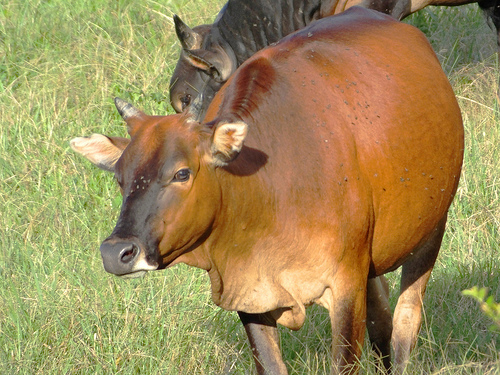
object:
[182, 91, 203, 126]
horn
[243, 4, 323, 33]
skin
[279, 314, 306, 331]
tip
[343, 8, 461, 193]
skin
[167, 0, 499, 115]
animal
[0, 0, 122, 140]
grass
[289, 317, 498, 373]
grass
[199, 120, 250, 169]
ear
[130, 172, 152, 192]
flies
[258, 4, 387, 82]
back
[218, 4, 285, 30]
neck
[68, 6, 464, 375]
animal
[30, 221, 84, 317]
grass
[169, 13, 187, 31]
top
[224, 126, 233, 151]
hair